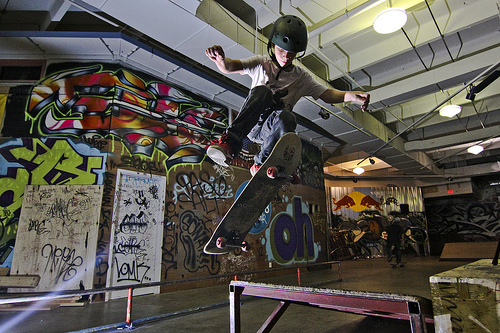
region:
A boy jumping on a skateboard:
[172, 11, 379, 258]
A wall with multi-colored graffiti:
[29, 68, 196, 179]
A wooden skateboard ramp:
[416, 245, 499, 331]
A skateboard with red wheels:
[198, 126, 307, 258]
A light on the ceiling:
[428, 93, 470, 122]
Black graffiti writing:
[28, 190, 90, 287]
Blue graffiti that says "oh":
[267, 190, 323, 270]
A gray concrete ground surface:
[144, 288, 191, 314]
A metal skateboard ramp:
[220, 274, 426, 331]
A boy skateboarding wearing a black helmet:
[180, 10, 379, 255]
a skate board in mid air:
[195, 132, 308, 267]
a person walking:
[375, 211, 405, 263]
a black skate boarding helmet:
[265, 15, 310, 55]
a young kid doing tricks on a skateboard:
[186, 15, 363, 185]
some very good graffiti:
[37, 71, 197, 156]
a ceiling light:
[357, 9, 426, 46]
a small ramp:
[220, 280, 415, 332]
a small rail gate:
[121, 280, 148, 331]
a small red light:
[442, 185, 456, 197]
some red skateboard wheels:
[257, 160, 284, 181]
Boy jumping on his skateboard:
[206, 15, 353, 265]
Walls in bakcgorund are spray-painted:
[39, 64, 213, 176]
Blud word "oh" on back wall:
[270, 198, 322, 267]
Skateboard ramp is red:
[228, 278, 444, 330]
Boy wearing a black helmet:
[262, 13, 312, 63]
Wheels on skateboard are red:
[263, 165, 281, 181]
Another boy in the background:
[379, 215, 421, 271]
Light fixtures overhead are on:
[372, 6, 409, 36]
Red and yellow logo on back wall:
[335, 190, 384, 213]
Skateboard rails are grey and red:
[4, 283, 141, 309]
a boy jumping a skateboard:
[152, 13, 384, 268]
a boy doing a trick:
[191, 10, 378, 260]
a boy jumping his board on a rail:
[190, 11, 463, 300]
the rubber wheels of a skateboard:
[262, 165, 303, 190]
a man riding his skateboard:
[378, 215, 411, 274]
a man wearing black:
[381, 215, 410, 269]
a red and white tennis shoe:
[202, 133, 241, 175]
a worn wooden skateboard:
[203, 127, 304, 259]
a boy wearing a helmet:
[265, 11, 313, 80]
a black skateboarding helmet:
[267, 9, 314, 58]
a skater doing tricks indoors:
[5, 0, 498, 330]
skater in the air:
[187, 8, 379, 185]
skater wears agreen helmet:
[194, 5, 373, 187]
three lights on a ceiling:
[376, 8, 490, 174]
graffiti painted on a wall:
[2, 63, 336, 288]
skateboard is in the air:
[194, 128, 310, 265]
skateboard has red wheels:
[188, 128, 310, 262]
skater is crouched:
[199, 14, 381, 196]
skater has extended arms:
[191, 11, 382, 131]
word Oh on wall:
[253, 178, 331, 271]